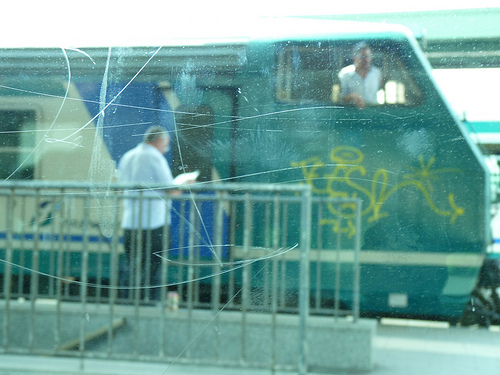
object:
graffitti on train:
[282, 142, 465, 248]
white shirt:
[328, 64, 388, 104]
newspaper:
[170, 169, 202, 192]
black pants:
[124, 223, 165, 297]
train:
[0, 36, 500, 324]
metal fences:
[1, 176, 361, 374]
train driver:
[326, 35, 386, 113]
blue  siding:
[77, 78, 227, 258]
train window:
[1, 106, 37, 185]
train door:
[148, 70, 239, 277]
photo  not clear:
[1, 2, 499, 373]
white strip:
[234, 246, 487, 267]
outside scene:
[0, 0, 500, 374]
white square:
[389, 292, 408, 310]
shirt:
[112, 140, 177, 230]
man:
[120, 125, 187, 305]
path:
[0, 294, 500, 375]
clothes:
[116, 143, 173, 232]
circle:
[328, 142, 367, 165]